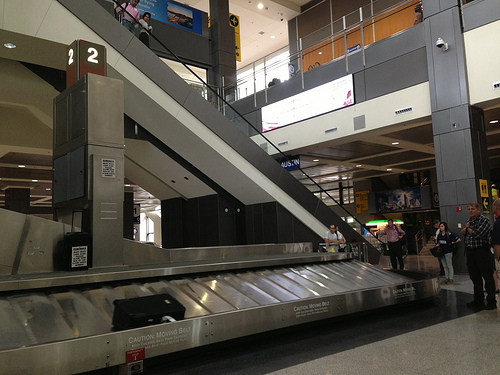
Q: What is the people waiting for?
A: Luggage.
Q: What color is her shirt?
A: Black.